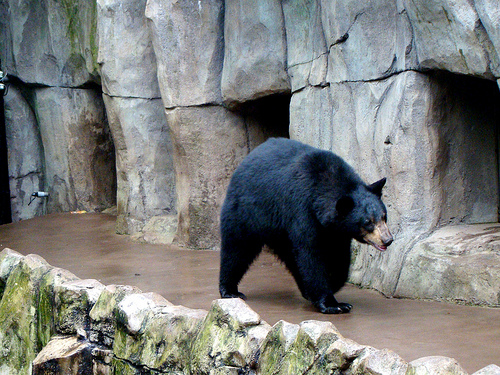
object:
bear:
[217, 136, 395, 314]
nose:
[380, 234, 392, 246]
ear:
[335, 193, 355, 219]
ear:
[366, 176, 387, 199]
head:
[312, 177, 393, 251]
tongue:
[379, 244, 387, 250]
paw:
[220, 288, 247, 301]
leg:
[220, 224, 264, 287]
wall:
[4, 2, 499, 309]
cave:
[421, 71, 500, 241]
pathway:
[0, 211, 500, 372]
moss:
[62, 1, 100, 65]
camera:
[26, 190, 47, 208]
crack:
[285, 8, 366, 71]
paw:
[314, 302, 342, 313]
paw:
[332, 302, 353, 313]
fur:
[219, 138, 353, 314]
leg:
[286, 220, 337, 305]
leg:
[316, 229, 352, 295]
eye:
[364, 218, 373, 226]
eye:
[382, 212, 386, 218]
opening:
[240, 92, 292, 163]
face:
[335, 176, 393, 252]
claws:
[337, 303, 353, 313]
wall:
[2, 244, 498, 374]